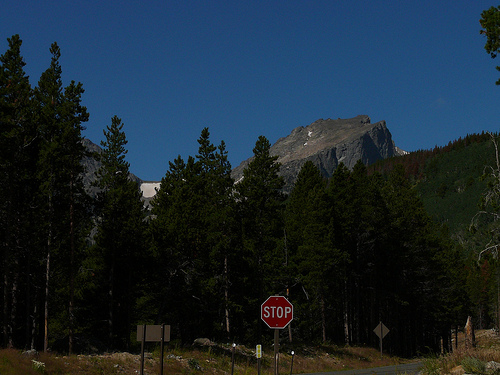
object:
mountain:
[65, 134, 142, 184]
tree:
[85, 114, 143, 355]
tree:
[139, 153, 211, 348]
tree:
[178, 126, 242, 346]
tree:
[231, 135, 292, 347]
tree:
[29, 41, 66, 350]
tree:
[58, 80, 98, 338]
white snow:
[304, 130, 316, 138]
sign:
[369, 320, 391, 340]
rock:
[223, 113, 398, 191]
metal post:
[138, 323, 147, 374]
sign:
[134, 323, 171, 342]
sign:
[259, 295, 294, 328]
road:
[283, 360, 435, 374]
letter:
[269, 305, 276, 319]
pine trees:
[0, 32, 36, 349]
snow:
[138, 182, 161, 198]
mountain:
[228, 114, 397, 193]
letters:
[274, 305, 282, 319]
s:
[261, 304, 271, 319]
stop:
[261, 305, 294, 319]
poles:
[157, 325, 165, 375]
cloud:
[0, 0, 499, 183]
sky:
[0, 0, 499, 183]